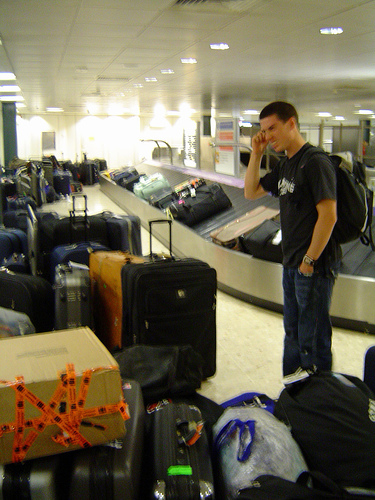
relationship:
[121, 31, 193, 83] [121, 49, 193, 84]
ceiling on ceiling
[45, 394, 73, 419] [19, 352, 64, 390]
tape on box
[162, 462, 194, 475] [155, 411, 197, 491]
tag on suitcase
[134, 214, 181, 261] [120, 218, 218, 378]
handle on bag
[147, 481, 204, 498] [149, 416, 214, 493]
tips on suitcase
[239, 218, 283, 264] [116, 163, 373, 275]
baggage claim on revolving belt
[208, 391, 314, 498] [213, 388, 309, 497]
bag on bag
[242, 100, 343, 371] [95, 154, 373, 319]
man at baggage claim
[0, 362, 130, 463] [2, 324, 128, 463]
tape wrapped around box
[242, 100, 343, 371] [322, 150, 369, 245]
man has a back pack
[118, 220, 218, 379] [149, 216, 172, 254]
bag with handle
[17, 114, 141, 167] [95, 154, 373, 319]
windows to baggage claim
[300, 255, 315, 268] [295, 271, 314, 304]
wrist watch in pocket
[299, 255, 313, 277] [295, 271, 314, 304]
hand in pocket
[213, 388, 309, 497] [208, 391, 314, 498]
bag with bag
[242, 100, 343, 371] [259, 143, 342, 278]
man wearing a shirt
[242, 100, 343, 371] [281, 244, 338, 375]
man wearing jeans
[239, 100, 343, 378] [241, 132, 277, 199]
man has arm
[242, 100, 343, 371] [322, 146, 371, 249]
man wearing a backpack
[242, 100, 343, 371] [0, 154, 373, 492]
man looking at luggage